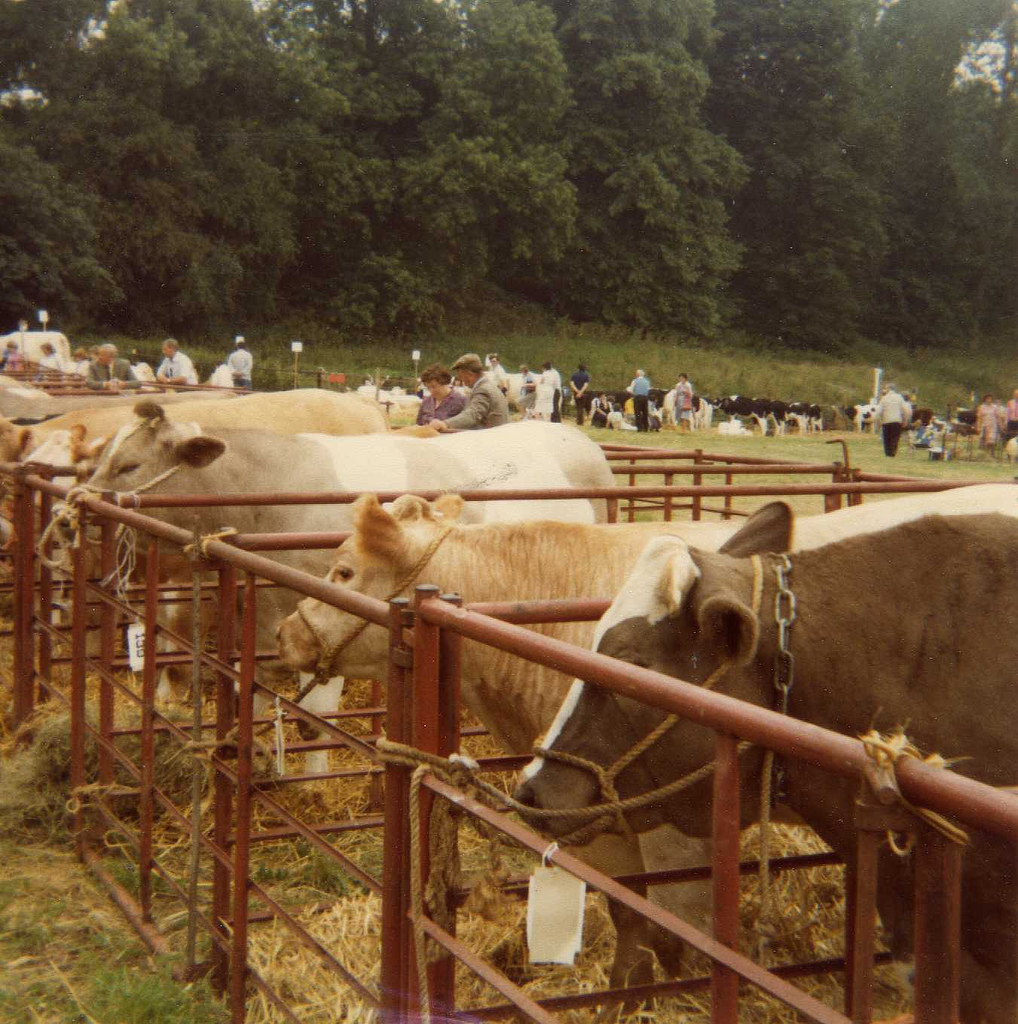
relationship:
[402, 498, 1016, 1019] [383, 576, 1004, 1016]
cow standing by cage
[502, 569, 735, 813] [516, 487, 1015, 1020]
face of cow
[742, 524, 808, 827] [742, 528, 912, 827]
chain around h neck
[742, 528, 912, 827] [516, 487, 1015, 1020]
neck of cow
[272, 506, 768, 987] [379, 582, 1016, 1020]
cow standing by cage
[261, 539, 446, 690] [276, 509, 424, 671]
rope around her face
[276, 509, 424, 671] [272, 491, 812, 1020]
face of cow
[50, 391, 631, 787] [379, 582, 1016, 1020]
cow standing by cage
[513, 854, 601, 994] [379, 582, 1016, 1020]
tag hanging from cage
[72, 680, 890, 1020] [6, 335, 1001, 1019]
hay on ground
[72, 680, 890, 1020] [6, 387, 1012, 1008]
hay under cows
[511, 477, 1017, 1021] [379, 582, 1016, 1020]
cow in cage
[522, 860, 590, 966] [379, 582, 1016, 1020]
tag hanging from cage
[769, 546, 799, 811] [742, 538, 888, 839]
chain around neck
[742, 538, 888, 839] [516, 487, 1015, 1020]
neck of cow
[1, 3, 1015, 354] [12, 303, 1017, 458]
trees behind crowd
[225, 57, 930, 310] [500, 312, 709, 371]
trees on the hill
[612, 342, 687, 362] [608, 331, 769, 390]
grass on the hill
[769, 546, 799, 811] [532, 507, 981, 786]
chain on the cow